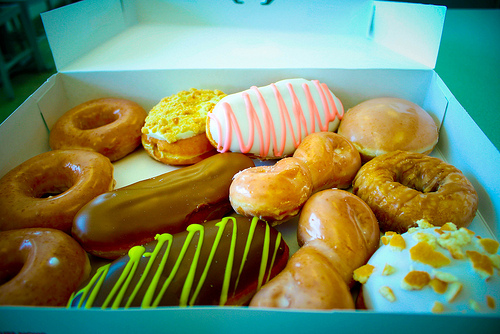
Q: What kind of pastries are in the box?
A: Donuts.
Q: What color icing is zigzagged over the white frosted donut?
A: Pink.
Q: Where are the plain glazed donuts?
A: Left.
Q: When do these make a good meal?
A: Breakfast.